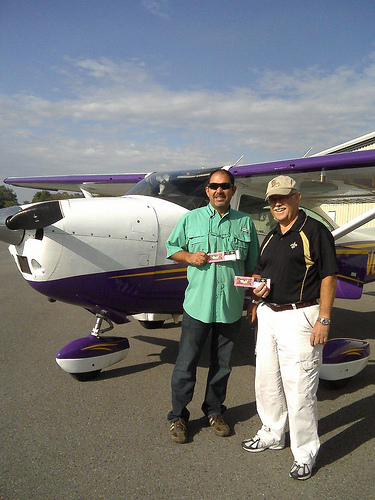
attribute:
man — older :
[229, 167, 339, 493]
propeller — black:
[3, 189, 72, 237]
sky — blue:
[70, 51, 299, 124]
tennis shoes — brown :
[167, 410, 232, 444]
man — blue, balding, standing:
[165, 166, 265, 443]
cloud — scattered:
[22, 137, 227, 167]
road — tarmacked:
[24, 384, 214, 498]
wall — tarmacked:
[177, 57, 216, 90]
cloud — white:
[7, 84, 73, 137]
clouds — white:
[77, 57, 156, 95]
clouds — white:
[0, 70, 372, 151]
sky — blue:
[0, 0, 373, 174]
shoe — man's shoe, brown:
[154, 405, 232, 447]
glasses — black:
[204, 180, 241, 193]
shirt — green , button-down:
[165, 203, 259, 323]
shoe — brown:
[153, 416, 205, 444]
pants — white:
[252, 297, 320, 465]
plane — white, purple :
[1, 149, 374, 399]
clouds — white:
[58, 52, 292, 168]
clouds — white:
[74, 55, 348, 145]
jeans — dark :
[165, 308, 240, 423]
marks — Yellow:
[84, 342, 120, 350]